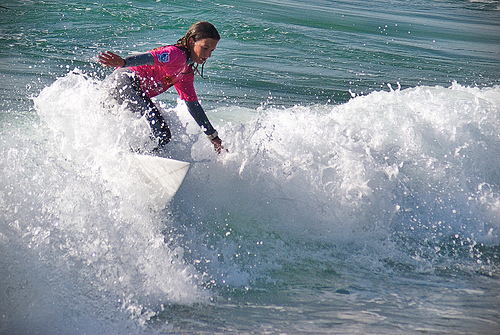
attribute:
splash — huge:
[237, 78, 484, 258]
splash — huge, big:
[2, 65, 497, 332]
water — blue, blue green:
[2, 0, 498, 331]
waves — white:
[1, 62, 497, 330]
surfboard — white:
[89, 144, 197, 221]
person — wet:
[100, 22, 233, 163]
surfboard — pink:
[108, 145, 194, 224]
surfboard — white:
[111, 149, 200, 220]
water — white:
[12, 203, 146, 320]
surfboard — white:
[79, 135, 274, 259]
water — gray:
[323, 268, 493, 333]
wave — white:
[21, 130, 181, 272]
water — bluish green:
[238, 5, 498, 88]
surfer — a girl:
[90, 22, 241, 174]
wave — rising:
[272, 101, 494, 251]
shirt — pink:
[100, 47, 232, 134]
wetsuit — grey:
[83, 45, 219, 181]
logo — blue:
[151, 46, 180, 66]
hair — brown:
[149, 10, 239, 48]